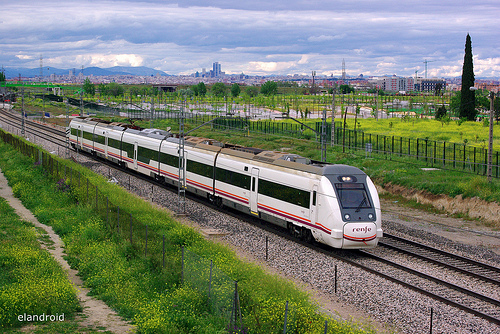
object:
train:
[65, 114, 384, 254]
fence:
[2, 96, 498, 333]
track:
[0, 110, 498, 328]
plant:
[0, 127, 357, 333]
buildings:
[0, 62, 498, 99]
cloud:
[4, 1, 497, 100]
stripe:
[62, 136, 381, 243]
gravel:
[0, 109, 497, 332]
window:
[81, 131, 94, 141]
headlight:
[341, 212, 351, 221]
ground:
[0, 92, 500, 333]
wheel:
[290, 221, 310, 243]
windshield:
[336, 187, 371, 209]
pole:
[171, 106, 192, 218]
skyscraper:
[194, 58, 231, 86]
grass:
[0, 137, 182, 332]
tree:
[457, 30, 480, 120]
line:
[374, 207, 500, 238]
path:
[379, 221, 500, 321]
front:
[324, 163, 385, 252]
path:
[0, 174, 136, 334]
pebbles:
[292, 251, 317, 272]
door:
[249, 169, 261, 216]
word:
[353, 225, 374, 233]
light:
[136, 91, 146, 98]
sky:
[1, 2, 499, 82]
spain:
[4, 60, 498, 332]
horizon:
[0, 69, 485, 101]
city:
[233, 73, 445, 83]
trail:
[0, 177, 126, 332]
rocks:
[317, 244, 481, 332]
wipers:
[354, 197, 367, 212]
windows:
[138, 147, 214, 179]